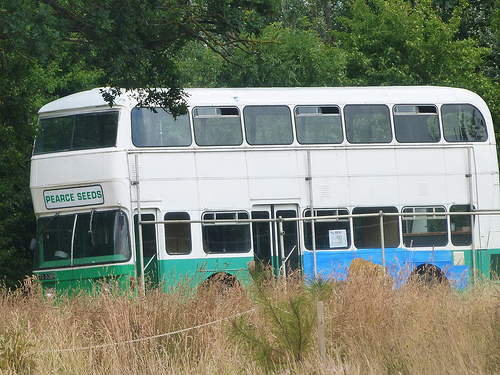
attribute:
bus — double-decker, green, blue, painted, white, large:
[31, 87, 500, 306]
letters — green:
[45, 187, 102, 208]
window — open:
[192, 105, 241, 146]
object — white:
[331, 229, 346, 249]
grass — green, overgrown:
[2, 277, 498, 373]